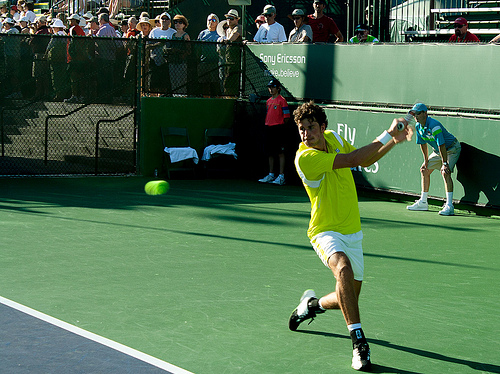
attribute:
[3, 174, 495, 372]
tennis court — hardcourt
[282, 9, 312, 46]
fans — taking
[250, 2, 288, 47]
fans — taking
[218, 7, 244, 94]
fans — taking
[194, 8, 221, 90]
fans — taking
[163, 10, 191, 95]
fans — taking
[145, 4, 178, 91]
fans — taking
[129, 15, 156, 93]
fans — taking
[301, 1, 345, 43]
fans — taking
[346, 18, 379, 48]
fans — taking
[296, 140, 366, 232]
man's shirt — yellow, white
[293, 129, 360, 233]
shirt — yellow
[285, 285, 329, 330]
tennis shoe — black, white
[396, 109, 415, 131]
racket — tennis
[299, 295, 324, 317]
socks — white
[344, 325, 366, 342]
socks — white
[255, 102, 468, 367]
tennis player — adult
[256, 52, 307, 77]
advertisement — Sony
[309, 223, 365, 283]
man's shorts — white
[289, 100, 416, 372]
man — running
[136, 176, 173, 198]
tennis ball — moving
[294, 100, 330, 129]
hair — curly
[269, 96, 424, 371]
athlete — male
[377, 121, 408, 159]
wrist band — white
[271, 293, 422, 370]
shoes — white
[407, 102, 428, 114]
hat — blue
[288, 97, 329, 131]
hair — brown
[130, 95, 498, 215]
wall — barrier